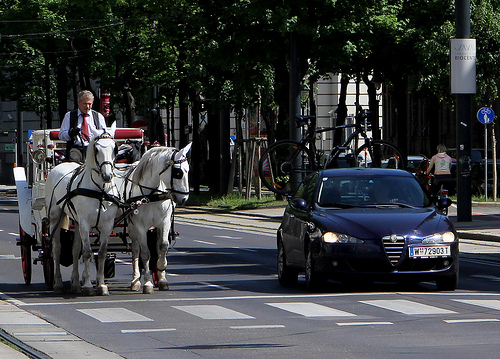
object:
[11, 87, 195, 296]
carriage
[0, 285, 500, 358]
sidewalk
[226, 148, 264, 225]
air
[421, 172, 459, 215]
bike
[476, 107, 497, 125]
road sign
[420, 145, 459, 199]
person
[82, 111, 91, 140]
tie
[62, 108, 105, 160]
vest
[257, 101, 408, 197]
bicycle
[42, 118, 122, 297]
horses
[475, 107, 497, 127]
sign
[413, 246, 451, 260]
tag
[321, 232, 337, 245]
lights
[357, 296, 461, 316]
paint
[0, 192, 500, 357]
road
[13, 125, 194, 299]
cart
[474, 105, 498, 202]
post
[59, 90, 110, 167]
man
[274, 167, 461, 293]
car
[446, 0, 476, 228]
posts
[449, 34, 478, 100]
stickers